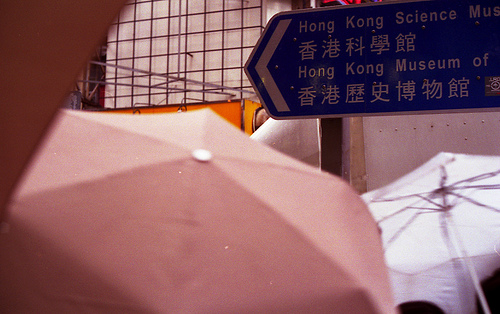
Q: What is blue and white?
A: A sign.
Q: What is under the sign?
A: Umbrellas.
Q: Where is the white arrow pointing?
A: To the museum.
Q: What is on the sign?
A: Honh Kong Museum of.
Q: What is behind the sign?
A: A wall.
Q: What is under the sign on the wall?
A: Ribbets in the wall.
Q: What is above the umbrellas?
A: A sign.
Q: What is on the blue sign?
A: Writing.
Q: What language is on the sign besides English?
A: Chinese.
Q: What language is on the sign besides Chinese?
A: English.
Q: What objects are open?
A: Umbrellas.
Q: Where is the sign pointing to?
A: To the left.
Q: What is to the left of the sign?
A: Metal mesh.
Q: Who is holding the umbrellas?
A: People in the rain.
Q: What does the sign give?
A: Direction.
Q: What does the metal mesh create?
A: Squares.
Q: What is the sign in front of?
A: A wall.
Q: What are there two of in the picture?
A: Umbrellas.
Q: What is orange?
A: The wall.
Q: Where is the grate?
A: On the wall.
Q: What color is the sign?
A: Blue.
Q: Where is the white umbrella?
A: Lower right quadrant.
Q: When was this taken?
A: Day time.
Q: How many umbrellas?
A: Two.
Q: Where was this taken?
A: Hong Kong.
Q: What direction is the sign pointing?
A: Left.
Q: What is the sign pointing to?
A: Museums.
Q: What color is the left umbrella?
A: Tan.